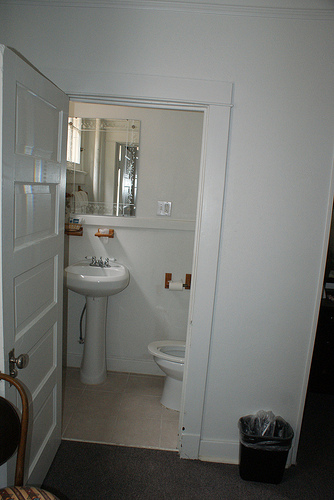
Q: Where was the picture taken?
A: An apartment.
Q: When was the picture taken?
A: Daytime.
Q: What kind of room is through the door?
A: A restroom.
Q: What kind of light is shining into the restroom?
A: Sunlight.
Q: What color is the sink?
A: White.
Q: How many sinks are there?
A: One.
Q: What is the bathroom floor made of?
A: Tile.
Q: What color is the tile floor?
A: Beige.